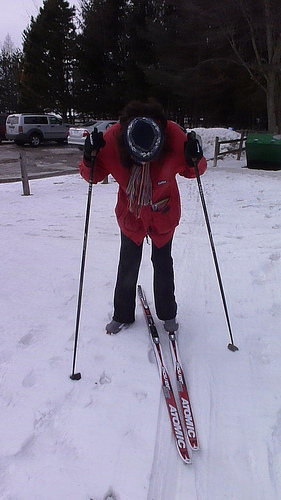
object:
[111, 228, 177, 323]
pants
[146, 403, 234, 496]
tracks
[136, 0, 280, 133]
tree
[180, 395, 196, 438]
word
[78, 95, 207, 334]
person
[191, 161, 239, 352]
pole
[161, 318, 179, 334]
shoes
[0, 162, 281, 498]
ground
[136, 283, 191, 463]
ski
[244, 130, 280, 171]
container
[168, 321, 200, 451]
ski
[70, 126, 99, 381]
ski poles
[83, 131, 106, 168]
hand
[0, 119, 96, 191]
parking lot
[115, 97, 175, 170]
hair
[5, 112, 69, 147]
vehicle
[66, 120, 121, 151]
vehicle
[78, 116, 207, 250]
coat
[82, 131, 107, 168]
gloves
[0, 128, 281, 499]
snow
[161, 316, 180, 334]
boot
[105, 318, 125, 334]
boot